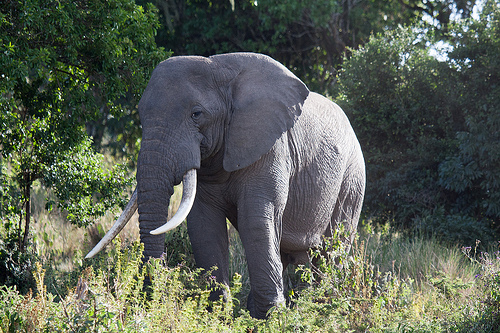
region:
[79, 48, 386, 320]
Elephant standing in clearing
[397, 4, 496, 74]
Patch of blue sky in background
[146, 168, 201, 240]
White ivory tusk of elephant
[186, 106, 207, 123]
Black eye of elephant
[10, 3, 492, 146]
Trees covered with leaves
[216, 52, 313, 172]
Alert grey ear of elephant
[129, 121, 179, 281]
Turnk of elephant hanging down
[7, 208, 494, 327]
Clearing covered with grasses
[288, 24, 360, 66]
Dead branches on trees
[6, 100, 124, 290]
Small tree in clearing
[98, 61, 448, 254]
a big grey elephant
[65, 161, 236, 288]
the big white tusk of an elephant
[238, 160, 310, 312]
the grey leg of an elephant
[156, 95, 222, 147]
eye of an elephant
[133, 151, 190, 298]
trunk of an elephant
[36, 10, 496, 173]
a heavily wooded area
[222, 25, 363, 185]
a big ear of an elephant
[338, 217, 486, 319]
weeds near an elephant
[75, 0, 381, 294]
a elephant in a wooded area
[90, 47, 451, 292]
a elephant standing in the woods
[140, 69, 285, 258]
Elephant looking bored.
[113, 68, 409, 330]
Elephant with tusk.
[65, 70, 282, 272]
Elephant next to tree.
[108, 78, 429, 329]
Elephant that is an adult elephant.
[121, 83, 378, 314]
A grey elephant.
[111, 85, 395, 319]
A clam elephant.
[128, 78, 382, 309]
An elephant standing up.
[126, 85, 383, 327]
Elephant walking through the grass.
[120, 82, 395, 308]
Elephant looking like it is bothered.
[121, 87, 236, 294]
Elephant with a trunk and tusk.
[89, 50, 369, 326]
Gray elephant standing in grass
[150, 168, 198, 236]
White tusk of gray elephant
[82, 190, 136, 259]
White tusk of gray elephant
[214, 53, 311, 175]
Large ear of elephant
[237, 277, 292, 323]
Foot of gray elephant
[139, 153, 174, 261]
Trunk of gray elephant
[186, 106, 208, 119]
Eye of gray elephant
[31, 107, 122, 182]
Green underbrush near elephant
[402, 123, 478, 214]
Green underbrush near elephant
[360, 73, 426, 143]
Green underbrush near elephant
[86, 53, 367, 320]
elephant in a sunlit field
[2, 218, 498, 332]
vegetation covering the ground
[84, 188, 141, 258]
long white pointed tusk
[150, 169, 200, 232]
curved white pointed tusk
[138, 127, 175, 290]
long gray wrinkled trunk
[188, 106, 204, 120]
small sad beady eye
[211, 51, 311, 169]
huge gray floppy ear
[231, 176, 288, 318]
long thick front leg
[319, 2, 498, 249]
full green bush behind the elephant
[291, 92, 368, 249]
massive gray elephant body